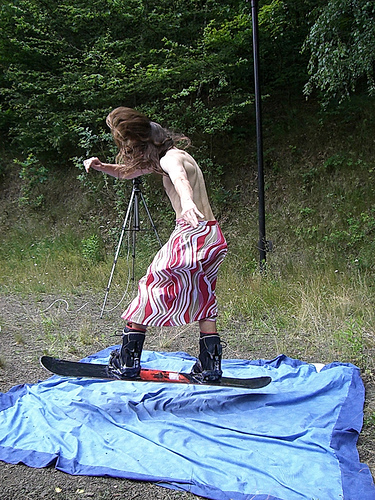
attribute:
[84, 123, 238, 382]
man — standing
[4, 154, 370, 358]
grass — standing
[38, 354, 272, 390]
skateboard — black, red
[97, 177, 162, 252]
tripod — on man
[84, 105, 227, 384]
man — muscular, thin, white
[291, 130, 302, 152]
ground — behind man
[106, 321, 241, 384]
boots — black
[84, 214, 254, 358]
dress — red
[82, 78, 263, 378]
man — standing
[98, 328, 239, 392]
boots — black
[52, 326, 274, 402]
skateboard — black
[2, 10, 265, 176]
tree — behind man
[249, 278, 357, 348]
grass — green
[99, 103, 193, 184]
mask — behind man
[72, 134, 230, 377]
man — standing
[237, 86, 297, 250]
pole — tall, black, metal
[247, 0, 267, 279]
pole — standing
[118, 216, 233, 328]
skirt — on man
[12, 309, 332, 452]
skate board — under man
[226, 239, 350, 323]
grass. — green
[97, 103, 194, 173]
hair — red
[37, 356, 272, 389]
snowboard — on man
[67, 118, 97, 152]
tree branch — behind man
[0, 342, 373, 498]
blanket — large , blue 